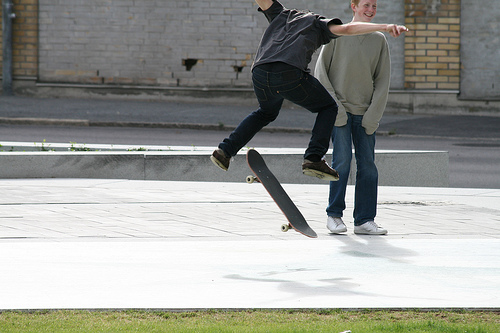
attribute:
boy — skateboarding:
[266, 7, 327, 69]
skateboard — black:
[239, 146, 320, 252]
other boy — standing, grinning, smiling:
[354, 0, 405, 97]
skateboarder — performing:
[221, 2, 345, 193]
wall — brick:
[413, 0, 449, 65]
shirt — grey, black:
[272, 12, 326, 79]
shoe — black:
[212, 145, 234, 174]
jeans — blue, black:
[224, 70, 336, 161]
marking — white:
[12, 136, 45, 153]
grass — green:
[64, 141, 92, 150]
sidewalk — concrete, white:
[128, 191, 205, 212]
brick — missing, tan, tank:
[426, 0, 443, 15]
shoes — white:
[323, 211, 387, 245]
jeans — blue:
[336, 112, 385, 221]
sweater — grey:
[322, 35, 414, 104]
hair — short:
[347, 1, 361, 10]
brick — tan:
[429, 46, 456, 67]